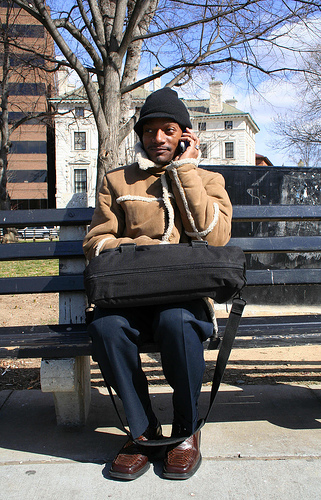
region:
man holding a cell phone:
[121, 88, 193, 166]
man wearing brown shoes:
[110, 424, 207, 488]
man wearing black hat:
[104, 88, 202, 156]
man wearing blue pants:
[98, 279, 207, 444]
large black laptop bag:
[87, 217, 247, 306]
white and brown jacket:
[106, 132, 222, 247]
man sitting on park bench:
[101, 84, 228, 326]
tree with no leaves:
[88, 0, 316, 97]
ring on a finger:
[182, 139, 203, 154]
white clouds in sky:
[228, 27, 309, 128]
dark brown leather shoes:
[107, 429, 206, 479]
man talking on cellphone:
[180, 118, 202, 162]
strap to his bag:
[58, 287, 251, 452]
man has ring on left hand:
[182, 135, 207, 158]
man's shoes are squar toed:
[105, 411, 234, 496]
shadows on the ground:
[230, 347, 319, 443]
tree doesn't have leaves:
[192, 4, 319, 94]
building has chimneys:
[189, 71, 254, 114]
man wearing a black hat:
[135, 70, 198, 139]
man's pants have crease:
[163, 294, 201, 439]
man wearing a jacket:
[76, 138, 257, 265]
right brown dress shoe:
[168, 435, 219, 478]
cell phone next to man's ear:
[171, 133, 204, 152]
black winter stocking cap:
[125, 89, 202, 127]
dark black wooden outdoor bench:
[262, 208, 318, 307]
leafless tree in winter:
[78, 10, 244, 96]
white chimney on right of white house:
[199, 79, 239, 114]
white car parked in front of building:
[21, 219, 70, 246]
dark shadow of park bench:
[245, 374, 315, 419]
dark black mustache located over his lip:
[145, 142, 179, 153]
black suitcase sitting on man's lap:
[90, 240, 278, 309]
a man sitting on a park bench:
[66, 92, 254, 484]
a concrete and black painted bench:
[1, 191, 318, 418]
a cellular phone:
[176, 135, 188, 153]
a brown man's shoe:
[99, 423, 158, 482]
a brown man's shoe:
[160, 416, 210, 482]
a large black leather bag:
[83, 243, 245, 446]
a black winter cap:
[129, 86, 189, 128]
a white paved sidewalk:
[3, 380, 319, 497]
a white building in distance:
[57, 72, 152, 204]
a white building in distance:
[165, 89, 254, 160]